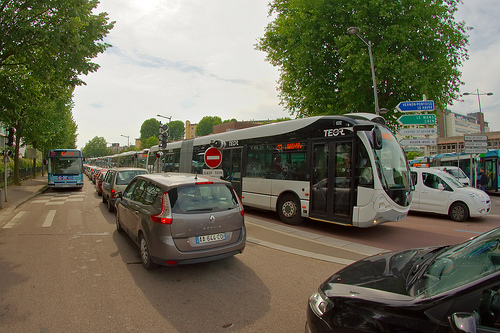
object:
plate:
[193, 231, 230, 243]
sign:
[203, 147, 225, 170]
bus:
[149, 115, 411, 228]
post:
[422, 95, 443, 159]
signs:
[391, 100, 441, 148]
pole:
[352, 27, 385, 117]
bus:
[49, 149, 84, 191]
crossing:
[22, 200, 136, 232]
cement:
[242, 213, 379, 264]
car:
[118, 173, 248, 269]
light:
[153, 122, 174, 163]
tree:
[267, 4, 472, 112]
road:
[16, 189, 312, 331]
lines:
[9, 209, 66, 232]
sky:
[87, 9, 281, 117]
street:
[246, 208, 498, 254]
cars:
[84, 162, 247, 265]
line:
[82, 158, 244, 261]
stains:
[70, 229, 110, 261]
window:
[170, 185, 237, 212]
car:
[407, 167, 491, 224]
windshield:
[367, 125, 415, 191]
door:
[310, 136, 352, 221]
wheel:
[273, 190, 307, 222]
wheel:
[447, 202, 470, 222]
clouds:
[158, 38, 234, 83]